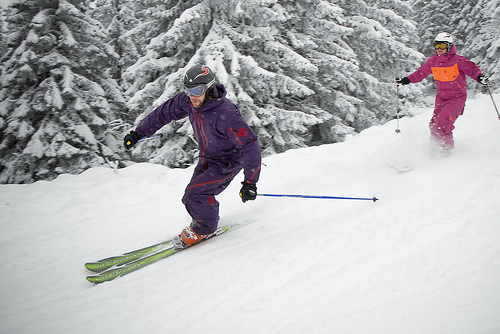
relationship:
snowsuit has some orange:
[406, 44, 481, 153] [430, 62, 467, 121]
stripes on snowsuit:
[182, 173, 232, 223] [135, 83, 261, 236]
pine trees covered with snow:
[0, 0, 499, 185] [0, 1, 498, 168]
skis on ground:
[85, 223, 236, 283] [1, 91, 500, 333]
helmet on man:
[183, 65, 220, 95] [124, 64, 261, 251]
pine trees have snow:
[0, 0, 499, 185] [0, 1, 498, 168]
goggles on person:
[431, 41, 453, 49] [398, 31, 490, 150]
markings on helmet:
[194, 65, 210, 83] [183, 65, 220, 95]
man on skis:
[124, 64, 261, 251] [85, 223, 236, 283]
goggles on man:
[181, 77, 216, 97] [124, 64, 261, 251]